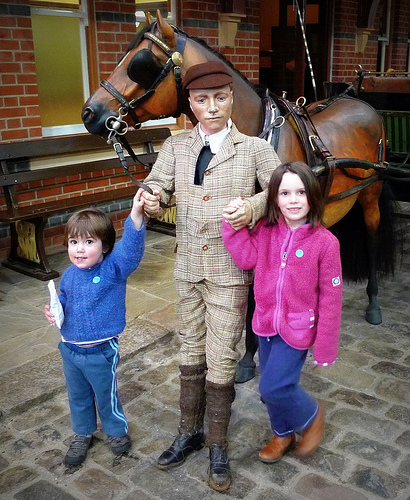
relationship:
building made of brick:
[2, 3, 408, 242] [2, 79, 25, 97]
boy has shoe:
[45, 186, 151, 469] [67, 435, 96, 467]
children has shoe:
[210, 156, 348, 464] [296, 401, 331, 455]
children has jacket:
[210, 156, 348, 464] [218, 213, 346, 369]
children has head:
[210, 156, 348, 464] [265, 161, 323, 225]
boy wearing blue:
[45, 186, 151, 469] [30, 213, 147, 430]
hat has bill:
[180, 60, 232, 93] [184, 75, 234, 92]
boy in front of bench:
[45, 186, 151, 469] [1, 121, 186, 283]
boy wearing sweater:
[45, 186, 151, 469] [53, 208, 154, 341]